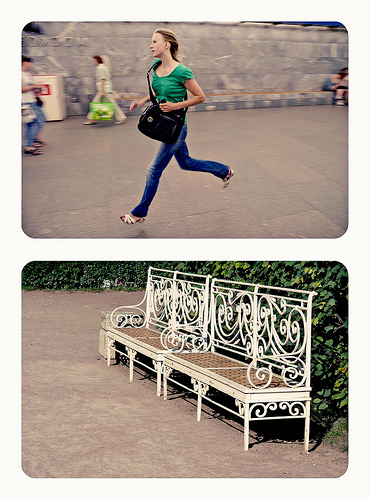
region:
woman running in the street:
[120, 22, 257, 224]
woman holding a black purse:
[142, 94, 187, 144]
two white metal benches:
[123, 271, 310, 429]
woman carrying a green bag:
[87, 95, 120, 125]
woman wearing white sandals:
[105, 166, 240, 231]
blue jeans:
[143, 142, 218, 189]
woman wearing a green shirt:
[149, 60, 190, 101]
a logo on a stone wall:
[24, 24, 91, 51]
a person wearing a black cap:
[21, 49, 35, 62]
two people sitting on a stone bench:
[322, 61, 354, 111]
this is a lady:
[138, 27, 241, 234]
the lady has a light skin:
[156, 45, 167, 57]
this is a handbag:
[145, 112, 175, 143]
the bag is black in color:
[156, 115, 175, 127]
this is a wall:
[234, 27, 311, 95]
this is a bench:
[126, 279, 298, 430]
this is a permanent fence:
[318, 266, 341, 407]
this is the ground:
[84, 396, 158, 460]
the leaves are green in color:
[48, 265, 87, 281]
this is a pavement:
[258, 107, 321, 204]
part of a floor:
[289, 117, 324, 161]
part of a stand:
[233, 418, 257, 456]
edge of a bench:
[211, 375, 244, 401]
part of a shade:
[308, 403, 328, 441]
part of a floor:
[136, 424, 167, 465]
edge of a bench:
[222, 365, 252, 407]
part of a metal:
[253, 366, 268, 385]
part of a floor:
[122, 414, 152, 442]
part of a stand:
[191, 381, 211, 406]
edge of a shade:
[305, 418, 331, 462]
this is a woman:
[118, 29, 244, 227]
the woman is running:
[120, 24, 241, 234]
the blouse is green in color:
[165, 79, 178, 94]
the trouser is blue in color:
[162, 149, 183, 157]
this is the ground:
[50, 398, 141, 462]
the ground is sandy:
[54, 382, 118, 456]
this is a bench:
[105, 263, 318, 445]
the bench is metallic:
[145, 281, 322, 441]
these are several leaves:
[320, 292, 344, 412]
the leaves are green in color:
[318, 305, 343, 392]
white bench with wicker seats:
[101, 261, 311, 448]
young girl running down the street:
[116, 25, 229, 219]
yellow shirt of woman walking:
[89, 64, 110, 89]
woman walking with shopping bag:
[84, 53, 122, 122]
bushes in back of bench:
[161, 259, 343, 415]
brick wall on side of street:
[29, 23, 345, 112]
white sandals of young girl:
[111, 205, 141, 221]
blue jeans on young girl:
[113, 118, 217, 207]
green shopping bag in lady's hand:
[83, 90, 108, 119]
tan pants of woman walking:
[87, 94, 125, 119]